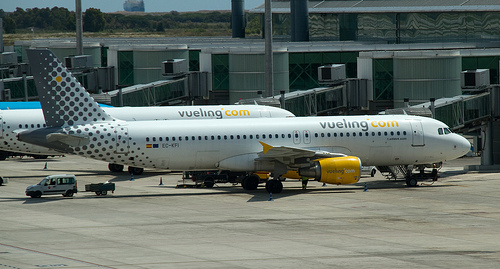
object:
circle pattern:
[32, 50, 108, 123]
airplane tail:
[18, 48, 118, 123]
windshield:
[438, 128, 444, 135]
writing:
[33, 262, 72, 267]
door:
[410, 120, 425, 147]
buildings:
[339, 47, 498, 123]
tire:
[406, 176, 417, 187]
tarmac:
[0, 159, 499, 266]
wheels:
[240, 176, 260, 190]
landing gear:
[265, 175, 284, 193]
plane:
[0, 100, 299, 150]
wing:
[252, 138, 348, 174]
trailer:
[85, 182, 114, 197]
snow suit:
[26, 174, 77, 198]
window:
[211, 135, 215, 139]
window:
[288, 134, 292, 138]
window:
[327, 133, 331, 137]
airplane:
[14, 42, 470, 195]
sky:
[2, 0, 259, 12]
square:
[141, 241, 290, 261]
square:
[343, 231, 498, 253]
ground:
[1, 151, 500, 269]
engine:
[305, 155, 364, 185]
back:
[104, 112, 439, 127]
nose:
[454, 133, 472, 161]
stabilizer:
[25, 48, 114, 126]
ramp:
[397, 81, 500, 145]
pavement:
[1, 153, 484, 266]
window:
[262, 134, 266, 138]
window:
[224, 135, 227, 139]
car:
[24, 174, 78, 197]